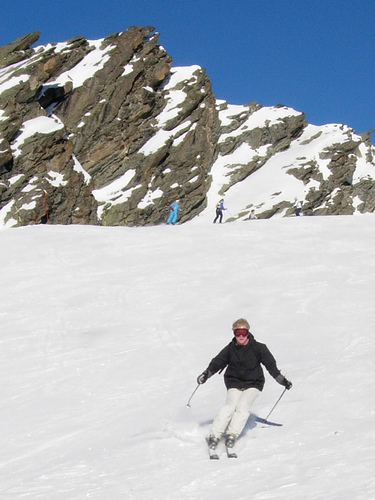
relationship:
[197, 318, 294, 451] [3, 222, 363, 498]
man skiing down slope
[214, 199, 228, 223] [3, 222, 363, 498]
person skiing down slope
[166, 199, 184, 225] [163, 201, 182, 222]
person in ski suit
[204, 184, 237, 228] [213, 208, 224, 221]
person wearing pants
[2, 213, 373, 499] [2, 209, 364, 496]
snow covering area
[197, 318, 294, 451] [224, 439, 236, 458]
man standing on ski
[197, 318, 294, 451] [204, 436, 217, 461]
man standing on ski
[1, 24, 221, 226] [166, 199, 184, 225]
rock behind person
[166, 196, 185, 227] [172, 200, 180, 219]
person wearing ski suit